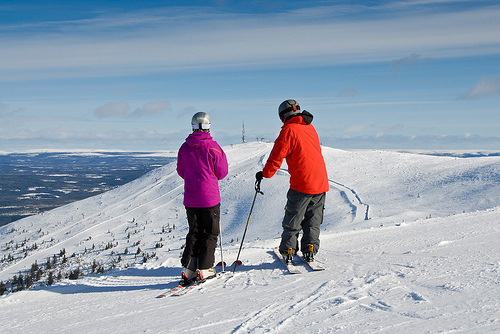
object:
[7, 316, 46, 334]
snow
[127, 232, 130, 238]
plants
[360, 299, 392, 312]
prints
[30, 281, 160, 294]
shadow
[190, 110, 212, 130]
helmet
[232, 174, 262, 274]
stick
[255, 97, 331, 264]
man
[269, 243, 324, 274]
skate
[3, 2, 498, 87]
sky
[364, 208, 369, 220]
mark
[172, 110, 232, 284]
woman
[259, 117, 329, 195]
jacket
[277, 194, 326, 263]
pants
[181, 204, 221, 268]
pants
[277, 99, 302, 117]
helmet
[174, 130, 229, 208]
jacket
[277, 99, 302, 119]
head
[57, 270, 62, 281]
tree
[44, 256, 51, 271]
tree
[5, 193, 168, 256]
down hill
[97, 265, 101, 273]
evergreen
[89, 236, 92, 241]
tree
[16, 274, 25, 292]
tree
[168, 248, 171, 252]
tree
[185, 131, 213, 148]
hoodie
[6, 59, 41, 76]
cloud